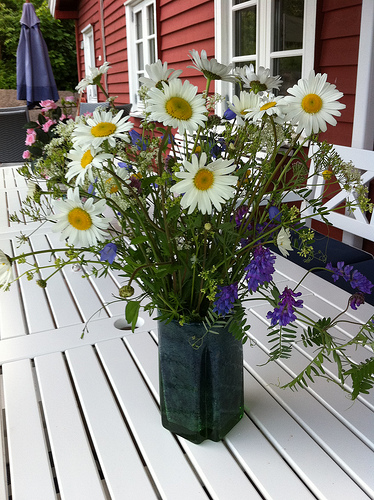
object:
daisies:
[241, 70, 346, 275]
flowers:
[138, 60, 183, 93]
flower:
[70, 109, 135, 151]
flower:
[212, 281, 239, 316]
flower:
[244, 244, 277, 292]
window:
[123, 0, 158, 105]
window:
[81, 22, 99, 104]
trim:
[126, 60, 160, 112]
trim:
[211, 60, 316, 146]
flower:
[280, 71, 346, 137]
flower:
[145, 78, 208, 136]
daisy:
[168, 150, 240, 218]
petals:
[254, 274, 263, 279]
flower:
[268, 204, 281, 227]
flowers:
[41, 118, 57, 133]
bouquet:
[0, 48, 373, 401]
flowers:
[51, 186, 110, 250]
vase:
[156, 308, 245, 445]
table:
[0, 159, 374, 500]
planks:
[11, 363, 138, 497]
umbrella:
[16, 3, 60, 110]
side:
[8, 4, 83, 233]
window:
[214, 1, 319, 121]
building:
[48, 0, 373, 250]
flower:
[265, 286, 303, 329]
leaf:
[267, 323, 299, 363]